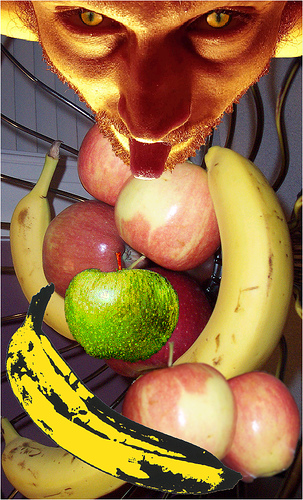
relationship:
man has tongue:
[35, 4, 245, 168] [130, 127, 175, 182]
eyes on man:
[69, 10, 251, 30] [35, 4, 245, 168]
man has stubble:
[35, 4, 245, 168] [174, 121, 203, 161]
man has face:
[35, 4, 245, 168] [60, 4, 237, 103]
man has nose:
[35, 4, 245, 168] [119, 60, 189, 147]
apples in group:
[53, 158, 217, 274] [12, 143, 283, 479]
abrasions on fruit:
[154, 174, 201, 250] [63, 250, 180, 365]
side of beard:
[23, 34, 89, 111] [42, 89, 269, 178]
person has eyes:
[35, 4, 245, 168] [69, 10, 251, 30]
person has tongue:
[35, 4, 245, 168] [130, 127, 175, 182]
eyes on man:
[69, 10, 251, 30] [8, 4, 297, 182]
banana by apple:
[202, 136, 288, 387] [122, 164, 223, 267]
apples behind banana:
[53, 158, 217, 274] [202, 136, 288, 387]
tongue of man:
[130, 127, 175, 182] [8, 4, 297, 182]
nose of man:
[119, 60, 189, 147] [8, 4, 297, 182]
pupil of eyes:
[85, 14, 100, 21] [69, 10, 251, 30]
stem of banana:
[20, 130, 62, 205] [14, 293, 243, 489]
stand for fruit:
[48, 320, 150, 420] [52, 195, 230, 403]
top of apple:
[128, 366, 229, 408] [124, 340, 229, 463]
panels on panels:
[2, 37, 96, 157] [2, 37, 96, 157]